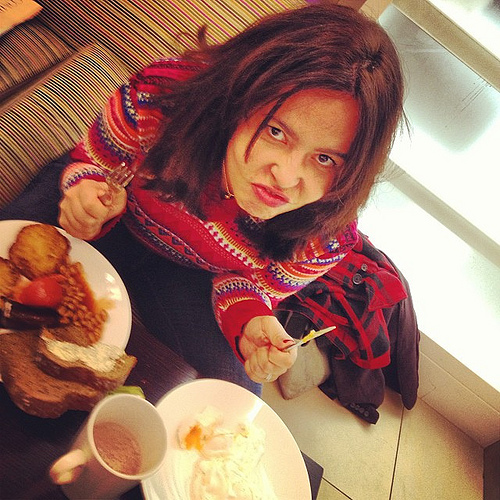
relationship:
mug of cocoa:
[47, 394, 168, 500] [94, 421, 139, 475]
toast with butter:
[3, 331, 138, 421] [45, 340, 115, 375]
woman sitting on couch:
[16, 9, 407, 403] [4, 1, 320, 211]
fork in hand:
[101, 162, 136, 207] [59, 179, 128, 242]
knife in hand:
[278, 324, 336, 354] [237, 315, 300, 386]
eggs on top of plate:
[162, 416, 276, 500] [140, 378, 313, 500]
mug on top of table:
[47, 394, 168, 500] [1, 320, 322, 500]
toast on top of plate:
[3, 331, 138, 421] [1, 220, 131, 352]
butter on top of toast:
[45, 340, 115, 375] [3, 331, 138, 421]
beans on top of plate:
[55, 266, 109, 349] [1, 220, 131, 352]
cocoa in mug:
[94, 421, 139, 475] [47, 394, 168, 500]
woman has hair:
[16, 9, 407, 403] [142, 6, 406, 269]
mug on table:
[47, 394, 168, 500] [1, 320, 322, 500]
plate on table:
[140, 378, 313, 500] [1, 320, 322, 500]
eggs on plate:
[162, 416, 276, 500] [140, 378, 313, 500]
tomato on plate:
[18, 278, 65, 307] [1, 220, 131, 352]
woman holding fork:
[16, 9, 407, 403] [101, 162, 136, 207]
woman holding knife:
[16, 9, 407, 403] [278, 324, 336, 354]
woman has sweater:
[16, 9, 407, 403] [59, 57, 358, 366]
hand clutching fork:
[59, 179, 128, 242] [101, 162, 136, 207]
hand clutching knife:
[237, 315, 300, 386] [278, 324, 336, 354]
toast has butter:
[3, 331, 138, 421] [45, 340, 115, 375]